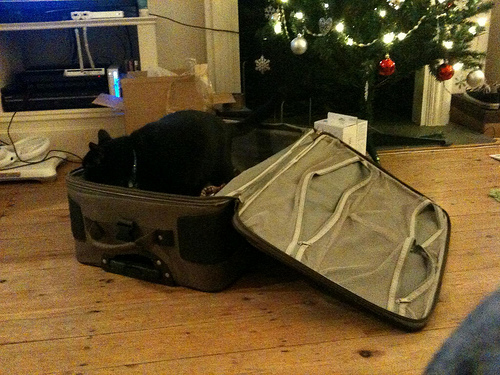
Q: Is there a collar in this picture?
A: Yes, there is a collar.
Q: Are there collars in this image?
A: Yes, there is a collar.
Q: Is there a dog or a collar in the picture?
A: Yes, there is a collar.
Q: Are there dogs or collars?
A: Yes, there is a collar.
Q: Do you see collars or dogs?
A: Yes, there is a collar.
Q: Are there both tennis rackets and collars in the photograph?
A: No, there is a collar but no rackets.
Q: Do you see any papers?
A: No, there are no papers.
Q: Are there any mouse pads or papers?
A: No, there are no papers or mouse pads.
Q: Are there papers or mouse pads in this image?
A: No, there are no papers or mouse pads.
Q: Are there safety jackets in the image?
A: No, there are no safety jackets.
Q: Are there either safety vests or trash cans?
A: No, there are no safety vests or trash cans.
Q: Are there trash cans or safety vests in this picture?
A: No, there are no safety vests or trash cans.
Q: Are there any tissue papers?
A: No, there are no tissue papers.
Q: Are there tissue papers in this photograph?
A: No, there are no tissue papers.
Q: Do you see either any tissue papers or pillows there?
A: No, there are no tissue papers or pillows.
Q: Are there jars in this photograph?
A: No, there are no jars.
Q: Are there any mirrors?
A: No, there are no mirrors.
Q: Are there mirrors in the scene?
A: No, there are no mirrors.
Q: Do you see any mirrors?
A: No, there are no mirrors.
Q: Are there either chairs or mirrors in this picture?
A: No, there are no mirrors or chairs.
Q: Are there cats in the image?
A: Yes, there is a cat.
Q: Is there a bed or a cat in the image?
A: Yes, there is a cat.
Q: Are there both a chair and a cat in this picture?
A: No, there is a cat but no chairs.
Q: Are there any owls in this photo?
A: No, there are no owls.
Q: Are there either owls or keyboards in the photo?
A: No, there are no owls or keyboards.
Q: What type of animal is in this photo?
A: The animal is a cat.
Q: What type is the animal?
A: The animal is a cat.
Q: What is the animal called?
A: The animal is a cat.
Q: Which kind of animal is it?
A: The animal is a cat.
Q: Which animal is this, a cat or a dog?
A: That is a cat.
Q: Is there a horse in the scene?
A: No, there are no horses.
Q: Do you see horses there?
A: No, there are no horses.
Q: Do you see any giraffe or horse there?
A: No, there are no horses or giraffes.